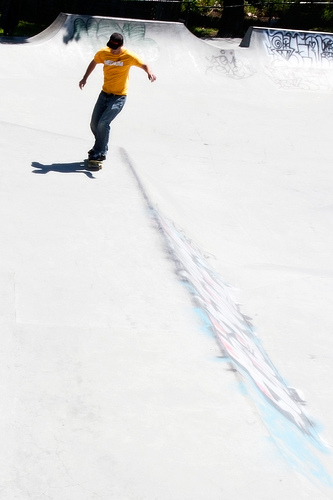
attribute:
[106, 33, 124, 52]
hat — black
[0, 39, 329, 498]
ramp — white ,  pointing downward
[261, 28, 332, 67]
black/white graffiti — black, white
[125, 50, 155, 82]
left arm — outstretched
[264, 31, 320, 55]
paint — Black , white 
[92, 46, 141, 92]
shirt — yellow 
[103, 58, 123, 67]
graphic — white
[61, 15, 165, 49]
graffiti — green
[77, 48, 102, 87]
arm — outstretched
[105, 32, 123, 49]
cap — black 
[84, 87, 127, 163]
jeans — blue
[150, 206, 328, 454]
graffiti — blue, white, red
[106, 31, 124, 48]
cap — Black 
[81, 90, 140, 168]
pants — blue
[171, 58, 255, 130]
skate park — large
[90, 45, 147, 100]
shirt — yellow 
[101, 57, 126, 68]
logo — white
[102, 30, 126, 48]
hat — black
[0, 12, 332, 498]
surface — white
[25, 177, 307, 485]
surface — white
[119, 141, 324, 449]
markings — dark